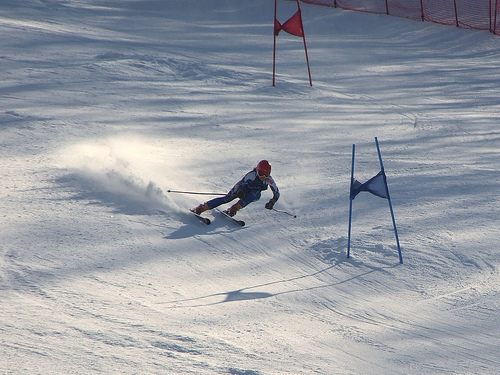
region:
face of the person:
[243, 151, 287, 183]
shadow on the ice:
[215, 260, 279, 318]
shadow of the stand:
[198, 250, 318, 342]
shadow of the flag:
[220, 265, 260, 330]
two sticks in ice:
[326, 208, 431, 270]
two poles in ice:
[321, 223, 417, 263]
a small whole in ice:
[161, 328, 217, 365]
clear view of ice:
[32, 245, 219, 357]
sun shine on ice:
[106, 252, 208, 332]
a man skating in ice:
[137, 124, 384, 293]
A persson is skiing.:
[168, 123, 289, 246]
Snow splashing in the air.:
[86, 132, 176, 194]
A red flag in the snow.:
[261, 7, 337, 87]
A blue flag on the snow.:
[339, 94, 422, 294]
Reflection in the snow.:
[158, 265, 310, 316]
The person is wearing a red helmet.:
[248, 153, 272, 169]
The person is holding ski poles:
[159, 171, 246, 206]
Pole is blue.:
[342, 139, 360, 270]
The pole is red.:
[263, 2, 287, 112]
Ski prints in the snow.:
[221, 237, 410, 355]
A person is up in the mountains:
[26, 7, 481, 372]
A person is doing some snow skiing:
[10, 15, 485, 353]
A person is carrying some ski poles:
[18, 20, 453, 371]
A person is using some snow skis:
[60, 13, 476, 370]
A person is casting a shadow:
[50, 15, 475, 372]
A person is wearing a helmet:
[33, 33, 466, 348]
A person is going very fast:
[25, 16, 480, 372]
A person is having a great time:
[27, 21, 467, 371]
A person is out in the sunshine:
[50, 58, 422, 371]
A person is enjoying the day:
[61, 34, 498, 345]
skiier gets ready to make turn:
[162, 159, 299, 244]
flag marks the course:
[268, 2, 314, 88]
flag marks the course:
[344, 135, 403, 267]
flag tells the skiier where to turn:
[266, 0, 316, 87]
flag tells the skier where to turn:
[342, 141, 403, 270]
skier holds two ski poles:
[164, 156, 297, 234]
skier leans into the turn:
[166, 159, 293, 228]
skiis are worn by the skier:
[185, 199, 245, 231]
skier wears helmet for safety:
[255, 159, 272, 180]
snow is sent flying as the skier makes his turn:
[68, 137, 198, 219]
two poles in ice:
[339, 129, 461, 300]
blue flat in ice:
[338, 155, 408, 220]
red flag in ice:
[261, 11, 329, 41]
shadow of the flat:
[203, 277, 278, 322]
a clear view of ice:
[38, 229, 250, 372]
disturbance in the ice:
[81, 114, 189, 226]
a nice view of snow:
[22, 21, 259, 103]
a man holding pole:
[161, 171, 233, 215]